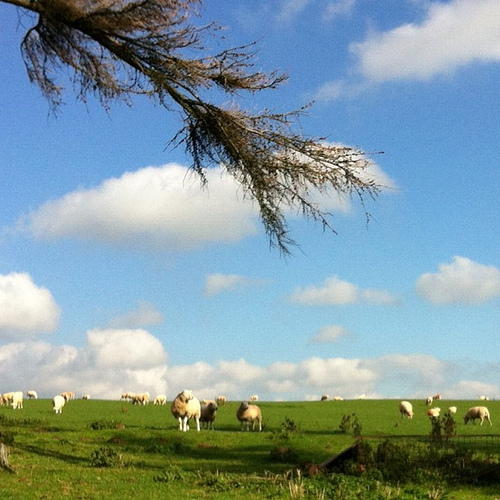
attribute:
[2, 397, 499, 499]
field — large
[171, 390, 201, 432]
sheep — white-fleeced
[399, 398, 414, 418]
sheep — white-fleeced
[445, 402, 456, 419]
sheep — white-fleeced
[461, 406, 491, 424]
sheep — white-fleeced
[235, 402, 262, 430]
sheep — white-fleeced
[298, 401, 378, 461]
bushes — little 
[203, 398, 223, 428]
sheep — white-fleeced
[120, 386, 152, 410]
sheep — white-fleeced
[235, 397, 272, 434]
sheep — white-fleeced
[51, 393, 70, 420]
sheep — white-fleeced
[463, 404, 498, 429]
sheep — white-fleeced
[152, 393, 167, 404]
sheep — white-fleeced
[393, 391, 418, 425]
sheep — white-fleeced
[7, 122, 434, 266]
clouds — fluffy 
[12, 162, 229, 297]
sky — blue 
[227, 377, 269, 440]
sheep — white-fleeced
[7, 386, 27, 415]
sheep — white-fleeced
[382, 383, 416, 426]
sheep — white-fleeced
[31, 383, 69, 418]
sheep — white-fleeced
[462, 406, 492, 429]
sheep — white-fleeced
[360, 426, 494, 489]
fence — small